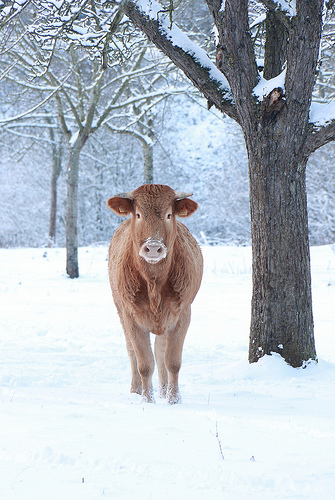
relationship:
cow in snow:
[94, 182, 217, 408] [5, 247, 334, 447]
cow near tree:
[94, 182, 217, 408] [121, 0, 323, 371]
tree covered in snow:
[121, 0, 323, 371] [5, 247, 334, 447]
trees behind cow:
[1, 0, 169, 292] [94, 182, 217, 408]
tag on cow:
[115, 204, 188, 218] [94, 182, 217, 408]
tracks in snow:
[40, 309, 189, 408] [5, 247, 334, 447]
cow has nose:
[94, 182, 217, 408] [141, 243, 167, 260]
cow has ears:
[94, 182, 217, 408] [101, 193, 199, 221]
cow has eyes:
[94, 182, 217, 408] [132, 206, 177, 227]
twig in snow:
[36, 248, 55, 262] [5, 247, 334, 447]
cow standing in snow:
[94, 182, 217, 408] [5, 247, 334, 447]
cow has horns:
[94, 182, 217, 408] [113, 189, 197, 201]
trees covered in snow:
[1, 0, 169, 292] [5, 247, 334, 447]